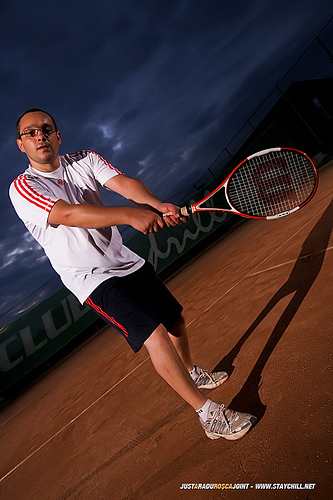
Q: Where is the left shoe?
A: On the left foot.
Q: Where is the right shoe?
A: On the right foot.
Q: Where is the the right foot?
A: In the right shoe.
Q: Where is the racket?
A: In the man's hand.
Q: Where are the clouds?
A: In the sky.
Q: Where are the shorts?
A: On the man.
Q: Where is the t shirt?
A: On the man.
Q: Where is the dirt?
A: On the ground.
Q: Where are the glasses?
A: On the man.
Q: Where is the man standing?
A: On a tennis court.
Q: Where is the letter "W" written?
A: On tennis racket.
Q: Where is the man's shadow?
A: On the court.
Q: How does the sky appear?
A: Very cloudy.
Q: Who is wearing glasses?
A: The tennis player.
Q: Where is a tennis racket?
A: In man's hands.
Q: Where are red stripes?
A: On man's shirt.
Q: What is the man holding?
A: Tennis racquet.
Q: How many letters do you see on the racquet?
A: 1.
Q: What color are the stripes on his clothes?
A: Red.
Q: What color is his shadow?
A: Black.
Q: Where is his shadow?
A: Ground.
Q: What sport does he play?
A: Tennis.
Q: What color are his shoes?
A: White.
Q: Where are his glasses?
A: Face.